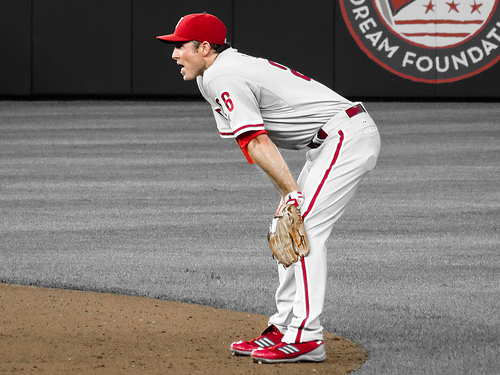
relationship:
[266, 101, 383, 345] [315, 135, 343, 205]
pants with red stripe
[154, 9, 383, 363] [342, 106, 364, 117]
man wearing red belt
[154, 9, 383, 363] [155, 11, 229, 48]
man wearing cap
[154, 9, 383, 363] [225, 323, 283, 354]
man wearing shoe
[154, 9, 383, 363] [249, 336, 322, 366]
man wearing shoe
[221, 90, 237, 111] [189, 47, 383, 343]
number on uniform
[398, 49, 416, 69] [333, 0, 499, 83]
letter on logo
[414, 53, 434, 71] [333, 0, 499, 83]
letter on logo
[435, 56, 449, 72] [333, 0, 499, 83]
letter on logo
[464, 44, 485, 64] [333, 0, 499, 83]
letter on logo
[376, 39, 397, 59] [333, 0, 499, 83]
letter on logo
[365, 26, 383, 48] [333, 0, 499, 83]
letter on logo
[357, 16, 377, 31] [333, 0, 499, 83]
letter on logo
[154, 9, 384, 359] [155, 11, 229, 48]
man wearing cap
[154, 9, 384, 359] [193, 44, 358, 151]
man wearing jersey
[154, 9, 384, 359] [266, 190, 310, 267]
man wearing glove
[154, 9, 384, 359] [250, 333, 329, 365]
man wearing shoe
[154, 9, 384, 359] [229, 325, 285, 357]
man wearing shoe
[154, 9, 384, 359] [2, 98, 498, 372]
man on field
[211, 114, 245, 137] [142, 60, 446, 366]
hat  player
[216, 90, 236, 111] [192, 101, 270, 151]
number on sleeve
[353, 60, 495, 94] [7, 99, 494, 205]
logo on wall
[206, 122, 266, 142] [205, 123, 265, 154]
stripes on sleeves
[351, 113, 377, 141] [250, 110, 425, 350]
pocket on pants